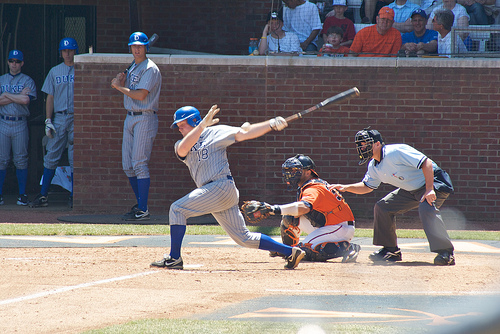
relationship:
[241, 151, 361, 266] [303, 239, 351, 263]
catcher has shin guards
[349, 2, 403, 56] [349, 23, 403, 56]
man wearing shirt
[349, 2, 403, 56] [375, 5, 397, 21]
man wearing hat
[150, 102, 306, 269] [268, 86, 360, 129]
baseball player holding bat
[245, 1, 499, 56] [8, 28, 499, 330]
people watching game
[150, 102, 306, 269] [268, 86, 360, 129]
man has bat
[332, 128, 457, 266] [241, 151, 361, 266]
umpire behind catcher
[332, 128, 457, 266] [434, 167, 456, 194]
umpire has bag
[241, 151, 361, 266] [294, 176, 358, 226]
catcher wearing shirt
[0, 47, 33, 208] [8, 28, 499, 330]
baseball player watching game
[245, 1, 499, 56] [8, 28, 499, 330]
crowd watching game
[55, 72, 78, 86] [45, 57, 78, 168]
school name written on uniform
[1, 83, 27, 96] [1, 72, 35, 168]
school name written on uniform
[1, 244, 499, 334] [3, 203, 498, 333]
dirt on baseball field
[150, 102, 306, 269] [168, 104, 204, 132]
baseball player has helmet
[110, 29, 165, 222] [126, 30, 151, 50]
baseball player has helmet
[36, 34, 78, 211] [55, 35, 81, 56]
baseball player has helmet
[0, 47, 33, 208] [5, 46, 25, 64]
baseball player has helmet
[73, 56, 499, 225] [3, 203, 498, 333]
wall by baseball field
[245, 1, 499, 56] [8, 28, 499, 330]
fans watching game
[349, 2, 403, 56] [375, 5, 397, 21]
man has hat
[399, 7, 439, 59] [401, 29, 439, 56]
man in shirt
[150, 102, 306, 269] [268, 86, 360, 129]
player has bat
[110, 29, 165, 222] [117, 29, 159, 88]
baseball player has bat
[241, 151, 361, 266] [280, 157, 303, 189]
player has headgear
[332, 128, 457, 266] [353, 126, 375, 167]
player has headgear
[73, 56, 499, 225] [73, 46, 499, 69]
brick wall has top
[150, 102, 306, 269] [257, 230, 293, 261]
baseball player has sock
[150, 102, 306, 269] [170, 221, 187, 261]
baseball player has sock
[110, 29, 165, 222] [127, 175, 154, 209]
baseball player has sock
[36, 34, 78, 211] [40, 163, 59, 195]
baseball player has sock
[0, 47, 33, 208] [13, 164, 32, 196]
baseball player has sock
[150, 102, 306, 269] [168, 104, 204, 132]
baseball player has hat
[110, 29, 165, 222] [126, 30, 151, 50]
baseball player has hat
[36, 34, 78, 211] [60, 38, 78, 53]
baseball player has hat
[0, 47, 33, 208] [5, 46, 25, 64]
baseball player has hat